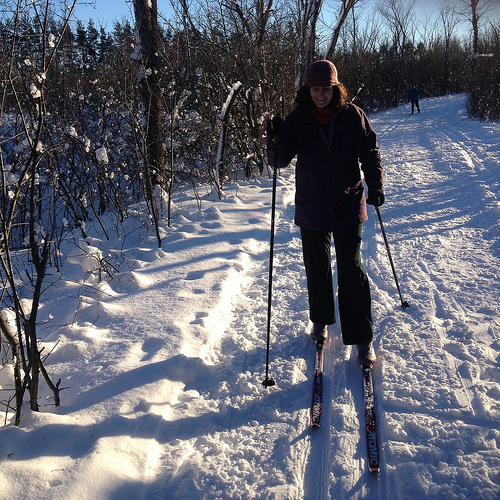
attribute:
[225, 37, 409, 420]
woman — skiing, smiling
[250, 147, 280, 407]
pole — black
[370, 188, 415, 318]
pole — black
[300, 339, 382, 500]
skis — red, white, thin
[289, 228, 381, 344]
snow pants — black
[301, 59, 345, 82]
hat — red, brown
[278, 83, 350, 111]
hair — dark, brown, curly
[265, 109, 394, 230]
snow jacket — brown, purple, dark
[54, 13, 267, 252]
trees — bare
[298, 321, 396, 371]
boots — white